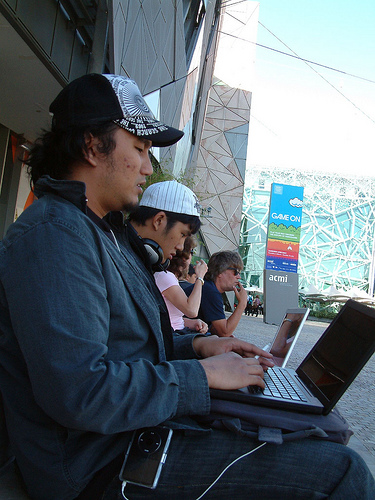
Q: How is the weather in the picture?
A: It is sunny.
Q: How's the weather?
A: It is sunny.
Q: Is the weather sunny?
A: Yes, it is sunny.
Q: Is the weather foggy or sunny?
A: It is sunny.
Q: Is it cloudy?
A: No, it is sunny.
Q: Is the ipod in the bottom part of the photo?
A: Yes, the ipod is in the bottom of the image.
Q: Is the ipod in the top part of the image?
A: No, the ipod is in the bottom of the image.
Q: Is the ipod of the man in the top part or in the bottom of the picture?
A: The ipod is in the bottom of the image.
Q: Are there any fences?
A: No, there are no fences.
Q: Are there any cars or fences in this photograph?
A: No, there are no fences or cars.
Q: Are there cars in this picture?
A: No, there are no cars.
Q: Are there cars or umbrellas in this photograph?
A: No, there are no cars or umbrellas.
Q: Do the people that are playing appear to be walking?
A: Yes, the people are walking.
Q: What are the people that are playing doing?
A: The people are walking.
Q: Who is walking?
A: The people are walking.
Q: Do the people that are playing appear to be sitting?
A: No, the people are walking.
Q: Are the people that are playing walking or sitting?
A: The people are walking.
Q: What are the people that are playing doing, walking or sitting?
A: The people are walking.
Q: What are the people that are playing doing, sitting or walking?
A: The people are walking.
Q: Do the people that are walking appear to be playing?
A: Yes, the people are playing.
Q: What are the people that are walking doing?
A: The people are playing.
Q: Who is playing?
A: The people are playing.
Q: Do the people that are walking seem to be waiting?
A: No, the people are playing.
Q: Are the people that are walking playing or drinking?
A: The people are playing.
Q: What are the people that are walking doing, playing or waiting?
A: The people are playing.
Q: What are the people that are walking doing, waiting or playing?
A: The people are playing.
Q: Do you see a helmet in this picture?
A: No, there are no helmets.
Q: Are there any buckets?
A: No, there are no buckets.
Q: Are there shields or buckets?
A: No, there are no buckets or shields.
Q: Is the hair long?
A: Yes, the hair is long.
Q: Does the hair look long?
A: Yes, the hair is long.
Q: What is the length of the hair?
A: The hair is long.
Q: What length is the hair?
A: The hair is long.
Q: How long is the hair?
A: The hair is long.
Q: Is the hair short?
A: No, the hair is long.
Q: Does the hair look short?
A: No, the hair is long.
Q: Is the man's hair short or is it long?
A: The hair is long.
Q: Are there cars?
A: No, there are no cars.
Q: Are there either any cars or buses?
A: No, there are no cars or buses.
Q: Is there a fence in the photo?
A: No, there are no fences.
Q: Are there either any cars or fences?
A: No, there are no fences or cars.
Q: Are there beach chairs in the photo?
A: No, there are no beach chairs.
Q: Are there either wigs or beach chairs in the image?
A: No, there are no beach chairs or wigs.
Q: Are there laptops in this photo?
A: Yes, there is a laptop.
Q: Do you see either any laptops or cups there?
A: Yes, there is a laptop.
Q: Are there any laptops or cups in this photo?
A: Yes, there is a laptop.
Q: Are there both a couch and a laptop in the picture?
A: No, there is a laptop but no couches.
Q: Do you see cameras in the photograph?
A: No, there are no cameras.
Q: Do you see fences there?
A: No, there are no fences.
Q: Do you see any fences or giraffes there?
A: No, there are no fences or giraffes.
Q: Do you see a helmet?
A: No, there are no helmets.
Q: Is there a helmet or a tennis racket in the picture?
A: No, there are no helmets or rackets.